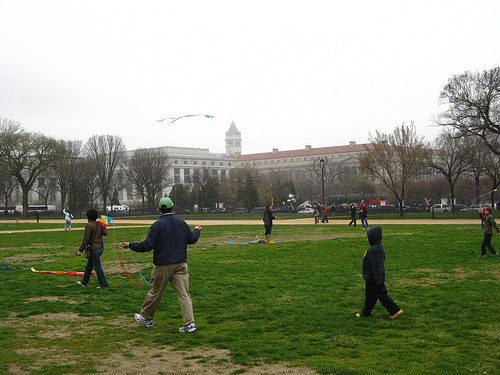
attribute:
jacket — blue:
[139, 221, 209, 257]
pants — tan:
[133, 262, 253, 362]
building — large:
[84, 114, 487, 218]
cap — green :
[154, 192, 176, 209]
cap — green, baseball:
[157, 195, 172, 210]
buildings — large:
[6, 139, 498, 206]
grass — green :
[3, 225, 497, 372]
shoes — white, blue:
[127, 312, 200, 336]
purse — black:
[78, 244, 97, 262]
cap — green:
[153, 194, 177, 213]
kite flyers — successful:
[114, 198, 205, 336]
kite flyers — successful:
[256, 195, 282, 242]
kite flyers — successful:
[71, 200, 117, 287]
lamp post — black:
[310, 148, 345, 229]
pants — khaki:
[138, 262, 198, 323]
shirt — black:
[352, 248, 393, 294]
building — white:
[147, 136, 394, 236]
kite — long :
[140, 80, 220, 136]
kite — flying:
[151, 102, 216, 141]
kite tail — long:
[28, 265, 98, 277]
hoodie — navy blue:
[362, 229, 386, 285]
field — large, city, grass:
[6, 214, 495, 374]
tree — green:
[358, 121, 434, 217]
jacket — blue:
[129, 214, 201, 264]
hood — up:
[363, 225, 382, 248]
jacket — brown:
[81, 217, 108, 255]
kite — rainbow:
[28, 260, 98, 277]